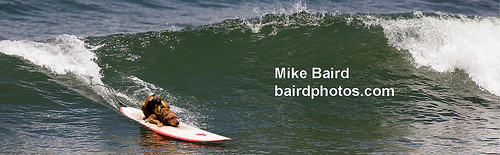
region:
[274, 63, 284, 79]
white letter on water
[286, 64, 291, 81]
white letter on water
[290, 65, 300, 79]
white letter on water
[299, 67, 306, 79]
white letter on water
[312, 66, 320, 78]
white letter on water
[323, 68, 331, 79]
white letter on water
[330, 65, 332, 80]
white letter on water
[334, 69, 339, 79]
white letter on water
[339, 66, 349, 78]
white letter on water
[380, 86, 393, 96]
white letter on water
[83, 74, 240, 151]
canine on a surf board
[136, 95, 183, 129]
canine resting on board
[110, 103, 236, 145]
surf board dog is resting on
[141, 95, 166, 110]
clothing on the dog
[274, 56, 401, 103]
credit for image for artist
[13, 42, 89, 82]
splash of water near canine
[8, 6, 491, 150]
body of water to surf in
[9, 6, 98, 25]
flat area of water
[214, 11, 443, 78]
curved area of water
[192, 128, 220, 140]
logo on the board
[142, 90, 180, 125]
a dog laying down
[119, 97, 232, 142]
a dog on a surf board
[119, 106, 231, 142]
a white and red surf board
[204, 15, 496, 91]
a large wave in the water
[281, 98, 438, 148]
greenish water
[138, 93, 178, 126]
a brown dog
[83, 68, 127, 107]
a cord coming off of the surf board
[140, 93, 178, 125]
a dog wearing a black vest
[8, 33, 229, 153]
a surf board that just went over a wave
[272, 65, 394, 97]
writing on the picture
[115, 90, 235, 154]
a dog laying on a surfboard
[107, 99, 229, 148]
a red and white surfboard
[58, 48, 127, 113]
the wake of a surfboard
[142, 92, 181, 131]
a dog with brown fur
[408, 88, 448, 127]
choppiness on the water's surface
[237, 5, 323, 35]
water splashing on the top of a wave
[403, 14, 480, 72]
white water cresting on a wave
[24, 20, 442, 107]
a wave in the ocean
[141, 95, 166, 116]
a dog with a harness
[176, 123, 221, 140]
the top of a surfboard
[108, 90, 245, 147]
dog on a surf board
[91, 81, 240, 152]
a dog surfing on a board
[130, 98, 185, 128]
a dog sitting on a board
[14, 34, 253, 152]
a dog is riding the wave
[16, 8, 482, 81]
waves of an ocean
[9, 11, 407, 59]
tides of an ocean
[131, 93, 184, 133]
dog wearing life vest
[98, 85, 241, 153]
surf board on water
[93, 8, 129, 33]
body of ocean water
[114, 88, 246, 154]
dog is laying down on board